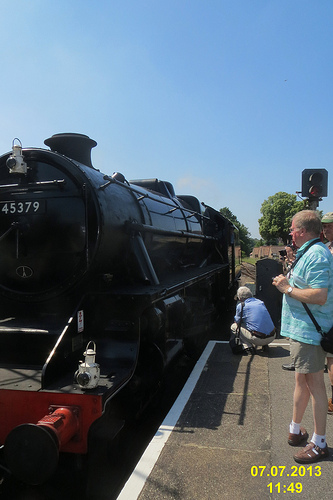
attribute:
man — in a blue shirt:
[229, 286, 278, 350]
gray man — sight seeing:
[229, 283, 279, 356]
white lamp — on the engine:
[69, 337, 109, 395]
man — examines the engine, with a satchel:
[231, 284, 277, 353]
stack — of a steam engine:
[43, 130, 98, 172]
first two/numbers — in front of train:
[0, 200, 16, 215]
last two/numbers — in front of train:
[24, 200, 40, 215]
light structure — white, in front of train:
[71, 338, 106, 394]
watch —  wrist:
[282, 287, 296, 295]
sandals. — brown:
[283, 427, 321, 462]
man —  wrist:
[287, 214, 320, 433]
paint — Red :
[1, 387, 85, 446]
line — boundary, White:
[121, 355, 197, 496]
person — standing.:
[233, 278, 273, 350]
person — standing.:
[278, 205, 322, 438]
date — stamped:
[247, 467, 323, 476]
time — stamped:
[254, 481, 306, 494]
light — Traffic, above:
[305, 173, 323, 197]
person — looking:
[286, 203, 322, 462]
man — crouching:
[234, 280, 272, 357]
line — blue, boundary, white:
[126, 339, 196, 493]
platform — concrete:
[161, 352, 282, 497]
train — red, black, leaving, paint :
[4, 159, 234, 471]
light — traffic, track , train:
[296, 173, 323, 200]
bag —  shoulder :
[285, 244, 323, 346]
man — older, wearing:
[280, 201, 322, 457]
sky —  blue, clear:
[21, 9, 322, 134]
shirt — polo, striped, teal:
[280, 238, 322, 346]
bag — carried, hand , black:
[286, 266, 322, 348]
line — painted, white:
[127, 343, 203, 495]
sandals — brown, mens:
[289, 430, 322, 463]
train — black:
[12, 138, 231, 463]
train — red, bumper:
[15, 146, 226, 478]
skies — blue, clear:
[0, 1, 322, 244]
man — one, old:
[270, 211, 331, 472]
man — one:
[279, 213, 331, 429]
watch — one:
[280, 279, 296, 298]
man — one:
[279, 205, 331, 466]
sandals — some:
[285, 426, 332, 470]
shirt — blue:
[280, 245, 331, 341]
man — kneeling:
[223, 270, 285, 369]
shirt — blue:
[229, 299, 289, 336]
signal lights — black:
[297, 162, 324, 218]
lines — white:
[131, 345, 226, 496]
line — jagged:
[174, 418, 312, 469]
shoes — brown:
[299, 442, 325, 468]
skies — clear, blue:
[36, 23, 258, 143]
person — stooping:
[221, 278, 290, 369]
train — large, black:
[33, 146, 241, 354]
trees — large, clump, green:
[255, 191, 310, 261]